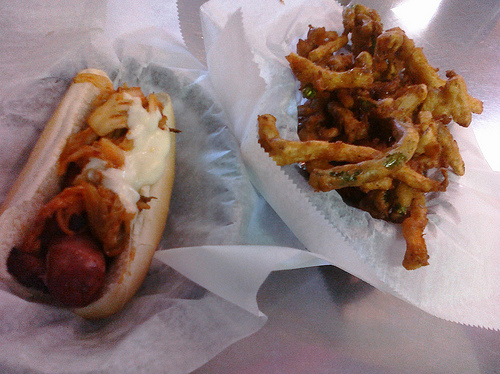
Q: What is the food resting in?
A: Paper.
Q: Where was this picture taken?
A: A restaurant.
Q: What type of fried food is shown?
A: Vegetables.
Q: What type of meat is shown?
A: Hot dog.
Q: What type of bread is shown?
A: Hot dog bun.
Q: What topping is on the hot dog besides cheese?
A: Chili.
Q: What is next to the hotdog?
A: Fries.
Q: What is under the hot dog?
A: Paper.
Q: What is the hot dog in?
A: Bun.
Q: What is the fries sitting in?
A: Basket.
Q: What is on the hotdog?
A: Topping.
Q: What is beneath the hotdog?
A: Tissue paper.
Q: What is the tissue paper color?
A: White paper.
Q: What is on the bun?
A: A hot dog and condiments.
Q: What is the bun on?
A: White translucent paper.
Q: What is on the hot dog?
A: White cheese.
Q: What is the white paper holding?
A: Food.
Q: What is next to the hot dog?
A: Fries.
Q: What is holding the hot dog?
A: A black dish with white paper.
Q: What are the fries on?
A: White translucent paper.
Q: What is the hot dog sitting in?
A: A hot dog bun.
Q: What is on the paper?
A: Hot dog and fries.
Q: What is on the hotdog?
A: Cheese.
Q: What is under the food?
A: Paper.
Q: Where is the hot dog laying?
A: Bun.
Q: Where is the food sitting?
A: Table.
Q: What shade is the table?
A: Silver.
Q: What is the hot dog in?
A: Bun.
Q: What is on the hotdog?
A: Cheese.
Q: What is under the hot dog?
A: Paper.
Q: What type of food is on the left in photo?
A: Hotdog.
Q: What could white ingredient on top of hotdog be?
A: Mayonaise.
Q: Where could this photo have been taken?
A: Restaurant.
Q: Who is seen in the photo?
A: Noone.